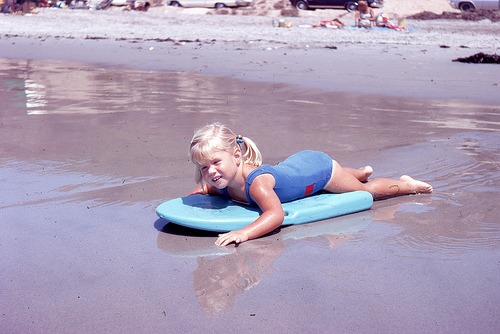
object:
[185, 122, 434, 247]
girl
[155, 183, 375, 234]
boogie board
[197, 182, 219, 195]
right arm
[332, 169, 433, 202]
left leg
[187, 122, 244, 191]
head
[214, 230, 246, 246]
hand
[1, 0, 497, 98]
beach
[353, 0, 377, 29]
person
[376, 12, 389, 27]
ball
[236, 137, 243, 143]
ponytail holder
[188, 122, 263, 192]
hair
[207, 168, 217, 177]
nose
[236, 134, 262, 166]
ponytail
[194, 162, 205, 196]
ponytail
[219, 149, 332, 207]
bathing suit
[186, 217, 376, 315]
reflection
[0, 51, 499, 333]
water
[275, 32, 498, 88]
sand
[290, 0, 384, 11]
car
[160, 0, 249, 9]
car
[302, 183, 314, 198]
decoration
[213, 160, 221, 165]
eye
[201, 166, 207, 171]
eye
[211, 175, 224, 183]
mouth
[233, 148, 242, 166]
ear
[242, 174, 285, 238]
left arm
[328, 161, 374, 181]
right leg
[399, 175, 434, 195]
foot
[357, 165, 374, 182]
foot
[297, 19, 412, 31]
blanket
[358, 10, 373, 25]
beach dress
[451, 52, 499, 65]
sea weed